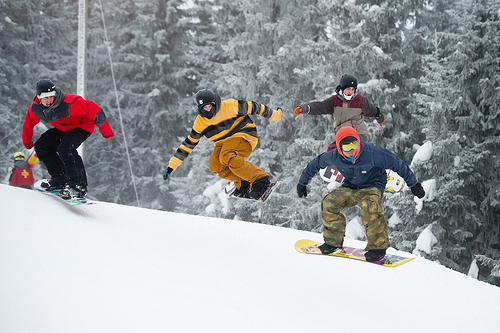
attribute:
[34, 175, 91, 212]
board — blue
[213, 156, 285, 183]
pants — brown 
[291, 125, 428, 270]
boy — snowboarding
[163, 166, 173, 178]
glove — black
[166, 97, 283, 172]
shirt — yellow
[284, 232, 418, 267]
board — yellow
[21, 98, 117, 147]
coat — gray, red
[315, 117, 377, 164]
hat — black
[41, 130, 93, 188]
pants — black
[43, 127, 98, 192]
pants — black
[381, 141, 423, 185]
arm — extended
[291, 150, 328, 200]
arm — extended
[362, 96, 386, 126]
arm — extended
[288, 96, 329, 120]
arm — extended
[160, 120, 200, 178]
arm — extended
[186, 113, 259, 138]
shirt — black, gray, yellow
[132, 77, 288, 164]
jacket — black, yellow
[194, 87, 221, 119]
hat — dark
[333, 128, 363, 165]
hat — black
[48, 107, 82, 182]
clothing — warm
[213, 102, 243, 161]
clothing — warm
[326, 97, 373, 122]
clothing — warm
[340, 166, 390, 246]
clothing — warm